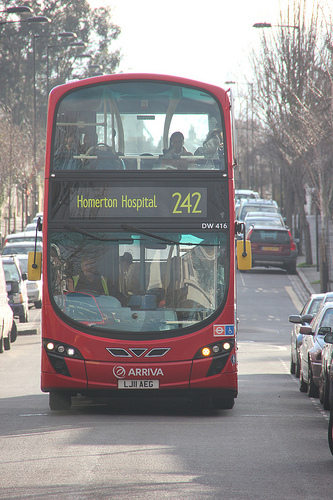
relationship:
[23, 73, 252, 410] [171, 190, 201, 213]
bus has 242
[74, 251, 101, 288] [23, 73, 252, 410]
driver of bus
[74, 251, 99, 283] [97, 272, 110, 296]
driver wearing vest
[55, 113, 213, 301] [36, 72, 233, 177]
people on level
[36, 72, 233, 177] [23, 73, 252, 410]
level of bus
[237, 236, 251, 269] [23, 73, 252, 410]
mirror on bus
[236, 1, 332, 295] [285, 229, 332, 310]
trees on sidewalk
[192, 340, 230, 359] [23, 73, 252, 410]
lights on bus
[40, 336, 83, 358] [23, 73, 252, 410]
lights on bus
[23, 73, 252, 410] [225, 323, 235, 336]
bus has handicap symbol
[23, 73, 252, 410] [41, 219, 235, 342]
bus has windshield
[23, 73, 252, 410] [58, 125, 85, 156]
bus has passenger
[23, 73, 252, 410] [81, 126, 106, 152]
bus has passenger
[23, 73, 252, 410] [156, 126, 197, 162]
bus has passenger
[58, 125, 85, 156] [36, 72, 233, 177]
passenger on level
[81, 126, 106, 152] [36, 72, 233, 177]
passenger on level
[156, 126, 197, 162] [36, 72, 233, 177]
passenger on level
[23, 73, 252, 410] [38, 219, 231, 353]
bus has level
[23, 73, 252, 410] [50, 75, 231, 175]
bus has level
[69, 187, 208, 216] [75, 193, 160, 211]
sign with letters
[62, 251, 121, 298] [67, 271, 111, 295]
passenger in safety vest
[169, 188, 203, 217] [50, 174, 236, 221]
242 on sign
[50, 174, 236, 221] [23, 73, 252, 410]
sign of bus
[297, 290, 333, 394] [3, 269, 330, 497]
cars on street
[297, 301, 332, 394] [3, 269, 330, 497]
cars on street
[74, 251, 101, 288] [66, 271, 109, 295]
driver has vest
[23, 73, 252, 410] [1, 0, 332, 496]
bus in city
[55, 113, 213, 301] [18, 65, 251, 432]
people in bus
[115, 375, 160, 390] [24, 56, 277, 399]
license plate on bus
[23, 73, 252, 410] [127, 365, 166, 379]
bus says arriva